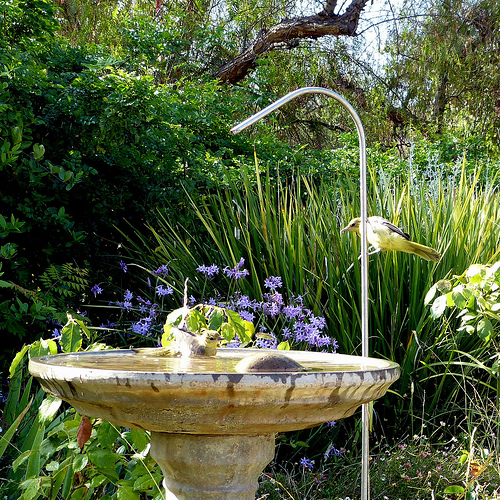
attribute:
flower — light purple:
[192, 263, 210, 277]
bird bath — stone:
[26, 319, 361, 487]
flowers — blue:
[238, 271, 343, 343]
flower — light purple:
[258, 273, 343, 335]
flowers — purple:
[84, 251, 333, 351]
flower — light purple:
[223, 331, 243, 350]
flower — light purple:
[280, 286, 306, 323]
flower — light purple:
[195, 262, 217, 277]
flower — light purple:
[151, 264, 168, 279]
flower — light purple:
[263, 273, 283, 291]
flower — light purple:
[235, 296, 250, 310]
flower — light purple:
[295, 329, 305, 341]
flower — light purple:
[219, 260, 249, 279]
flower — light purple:
[151, 281, 173, 297]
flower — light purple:
[88, 280, 104, 299]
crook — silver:
[223, 78, 393, 495]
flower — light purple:
[256, 268, 285, 298]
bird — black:
[129, 320, 225, 359]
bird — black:
[338, 212, 441, 262]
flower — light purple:
[263, 295, 285, 314]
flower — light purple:
[257, 272, 286, 292]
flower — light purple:
[193, 264, 210, 274]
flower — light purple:
[46, 328, 61, 342]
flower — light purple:
[115, 260, 130, 274]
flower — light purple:
[155, 282, 177, 301]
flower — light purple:
[115, 259, 133, 278]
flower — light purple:
[151, 282, 177, 296]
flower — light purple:
[235, 293, 256, 310]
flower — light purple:
[153, 261, 173, 282]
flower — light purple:
[119, 286, 136, 302]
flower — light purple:
[195, 257, 225, 277]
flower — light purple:
[189, 261, 225, 279]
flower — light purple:
[218, 254, 254, 282]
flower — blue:
[195, 261, 221, 279]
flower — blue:
[115, 260, 133, 277]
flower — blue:
[47, 326, 61, 343]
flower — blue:
[118, 289, 143, 300]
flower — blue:
[126, 316, 151, 340]